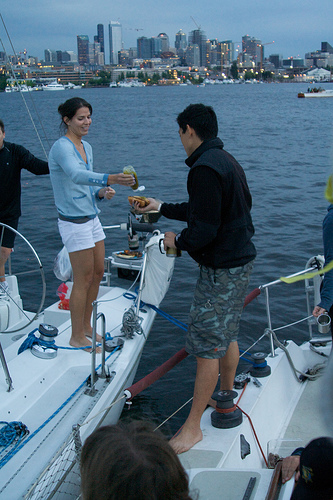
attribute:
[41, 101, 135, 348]
woman — young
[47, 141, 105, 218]
top — blue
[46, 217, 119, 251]
shorts — white, camouflage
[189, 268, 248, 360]
shorts — camouflage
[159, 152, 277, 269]
jacket — black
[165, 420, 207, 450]
foot — bear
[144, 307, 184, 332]
rope — blue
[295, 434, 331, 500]
hat — black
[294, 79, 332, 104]
boat — white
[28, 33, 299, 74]
buildings — tall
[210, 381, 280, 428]
boatties — boat ties